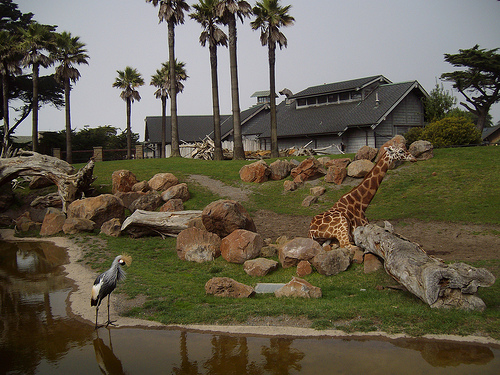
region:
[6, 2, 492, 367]
Would appear to be a zoo.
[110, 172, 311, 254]
Many rocks here.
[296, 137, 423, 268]
A giraffe takes it easy.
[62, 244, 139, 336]
Exotic birds preens itself.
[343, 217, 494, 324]
A lot of logs in the scene.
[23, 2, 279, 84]
Overcast sky makes it look cool.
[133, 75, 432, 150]
Building in the background.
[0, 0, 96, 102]
Aplm trees indicate a tropical climate.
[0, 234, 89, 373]
Muddy brown water.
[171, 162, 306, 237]
Looks like a well worn trail.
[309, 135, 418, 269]
giraffe is sitting down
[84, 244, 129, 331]
a bird near the water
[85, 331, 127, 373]
the bird's reflection in the water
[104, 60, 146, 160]
tall palm tree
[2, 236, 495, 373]
the water is brown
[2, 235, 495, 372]
the water looks dirty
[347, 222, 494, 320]
a large brown log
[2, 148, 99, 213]
a large brown log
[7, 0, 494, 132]
the sky is blue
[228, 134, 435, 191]
a row of orange and brown boulders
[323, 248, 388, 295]
part of some grass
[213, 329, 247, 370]
part of a water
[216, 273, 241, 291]
part of a stone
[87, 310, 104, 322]
part of some legs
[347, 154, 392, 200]
neck of a giraffe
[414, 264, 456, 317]
part of a log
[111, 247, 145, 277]
part of a head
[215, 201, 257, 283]
part of a rock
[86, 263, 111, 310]
chest of a bird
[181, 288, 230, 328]
part of a grass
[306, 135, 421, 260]
Giraffe laying down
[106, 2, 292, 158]
Tall palm trees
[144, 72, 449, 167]
Maintenance building with a dark grey roof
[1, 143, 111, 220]
Big rotten downed tree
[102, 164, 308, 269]
Boulders and an old tree limp in a grassy field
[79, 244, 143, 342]
Tall black, white, and grey bird wading on the waters edge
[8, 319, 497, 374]
Brown water along a shore line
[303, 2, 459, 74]
Grey sky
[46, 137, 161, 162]
Fence with large stone posts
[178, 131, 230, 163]
Chaotic log pile next to a tree trunk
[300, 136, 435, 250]
giraffe next to a log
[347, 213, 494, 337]
large log on ground next to giraffe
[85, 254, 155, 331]
bird standing on the edge of the water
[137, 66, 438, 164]
building on the top of the hill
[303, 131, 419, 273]
giraffe next to sandy pathway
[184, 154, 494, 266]
sandy pathway on the grass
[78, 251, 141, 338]
bird walking out of the water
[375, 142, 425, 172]
giraffes head pointing right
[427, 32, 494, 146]
larger tree to the right of the building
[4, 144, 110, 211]
large log to the left of the picture